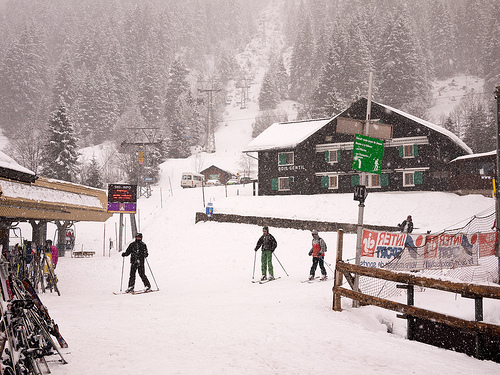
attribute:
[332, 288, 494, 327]
fence — brown wood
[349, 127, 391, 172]
sign — green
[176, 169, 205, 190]
van — white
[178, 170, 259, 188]
cars — parked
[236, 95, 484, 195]
ski lodge — brown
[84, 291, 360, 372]
snow — white